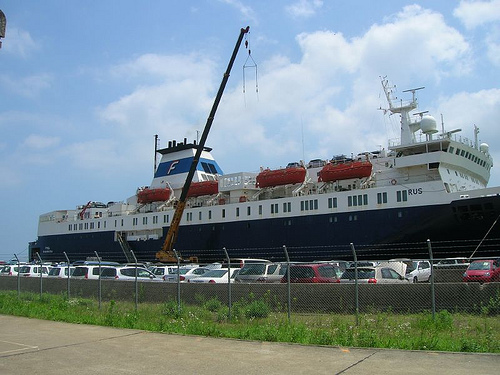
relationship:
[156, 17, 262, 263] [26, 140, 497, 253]
crane beside ship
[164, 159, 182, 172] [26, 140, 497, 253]
letter on side of ship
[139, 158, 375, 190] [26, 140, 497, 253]
rafts on top of ship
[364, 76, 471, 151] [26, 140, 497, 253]
radio equipment on top of ship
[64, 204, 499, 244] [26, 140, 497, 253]
balcony on side of ship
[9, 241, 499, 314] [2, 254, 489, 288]
fence behind cars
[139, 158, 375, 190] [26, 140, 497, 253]
rafts are on side of ship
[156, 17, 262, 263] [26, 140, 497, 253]
crane next to ship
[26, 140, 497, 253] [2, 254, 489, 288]
ship next to cars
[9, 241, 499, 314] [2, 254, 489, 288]
fence beside cars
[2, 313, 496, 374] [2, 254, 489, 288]
ground beside cars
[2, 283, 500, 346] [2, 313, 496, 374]
grass on top of ground